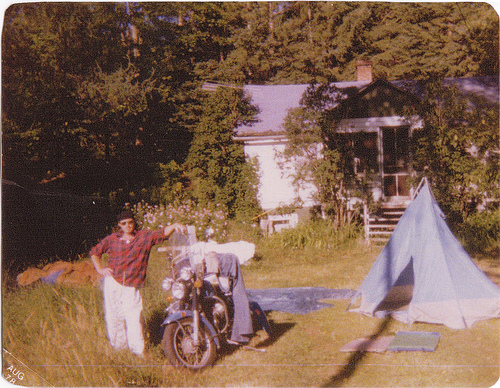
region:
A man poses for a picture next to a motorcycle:
[90, 211, 184, 356]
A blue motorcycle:
[160, 266, 265, 371]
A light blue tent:
[345, 175, 497, 327]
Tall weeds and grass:
[2, 281, 172, 384]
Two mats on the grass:
[347, 330, 439, 352]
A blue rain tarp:
[241, 288, 355, 310]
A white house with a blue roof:
[202, 58, 497, 243]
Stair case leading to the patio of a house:
[365, 204, 412, 245]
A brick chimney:
[353, 60, 375, 81]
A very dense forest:
[6, 5, 493, 212]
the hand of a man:
[158, 217, 183, 239]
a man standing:
[78, 208, 156, 353]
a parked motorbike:
[160, 235, 248, 372]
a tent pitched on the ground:
[391, 163, 492, 343]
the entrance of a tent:
[382, 263, 425, 327]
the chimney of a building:
[345, 45, 380, 77]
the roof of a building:
[238, 83, 300, 130]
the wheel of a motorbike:
[163, 320, 215, 372]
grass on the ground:
[2, 294, 94, 384]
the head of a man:
[120, 214, 140, 233]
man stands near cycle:
[79, 215, 168, 374]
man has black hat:
[106, 210, 140, 233]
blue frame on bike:
[140, 281, 215, 334]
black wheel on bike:
[155, 325, 211, 378]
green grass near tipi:
[431, 335, 473, 385]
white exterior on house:
[237, 128, 367, 232]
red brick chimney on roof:
[340, 48, 373, 83]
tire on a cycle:
[158, 316, 223, 375]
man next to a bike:
[72, 196, 185, 326]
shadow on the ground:
[316, 305, 408, 375]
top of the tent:
[375, 171, 455, 236]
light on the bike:
[157, 267, 192, 313]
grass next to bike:
[286, 318, 359, 383]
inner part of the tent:
[351, 240, 440, 335]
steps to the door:
[349, 186, 420, 249]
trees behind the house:
[92, 13, 409, 102]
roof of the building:
[201, 74, 337, 151]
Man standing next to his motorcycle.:
[90, 207, 271, 369]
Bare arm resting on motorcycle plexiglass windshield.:
[161, 222, 193, 257]